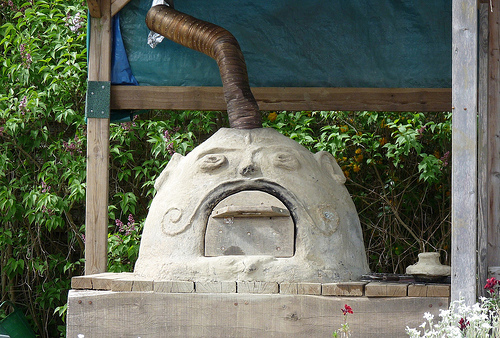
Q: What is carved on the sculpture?
A: A face.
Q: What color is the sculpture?
A: Grey.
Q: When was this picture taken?
A: Daytime.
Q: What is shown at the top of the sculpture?
A: An exhaust tube.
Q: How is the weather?
A: Clear.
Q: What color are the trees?
A: Green.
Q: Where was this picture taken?
A: A park.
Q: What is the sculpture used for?
A: Baking.